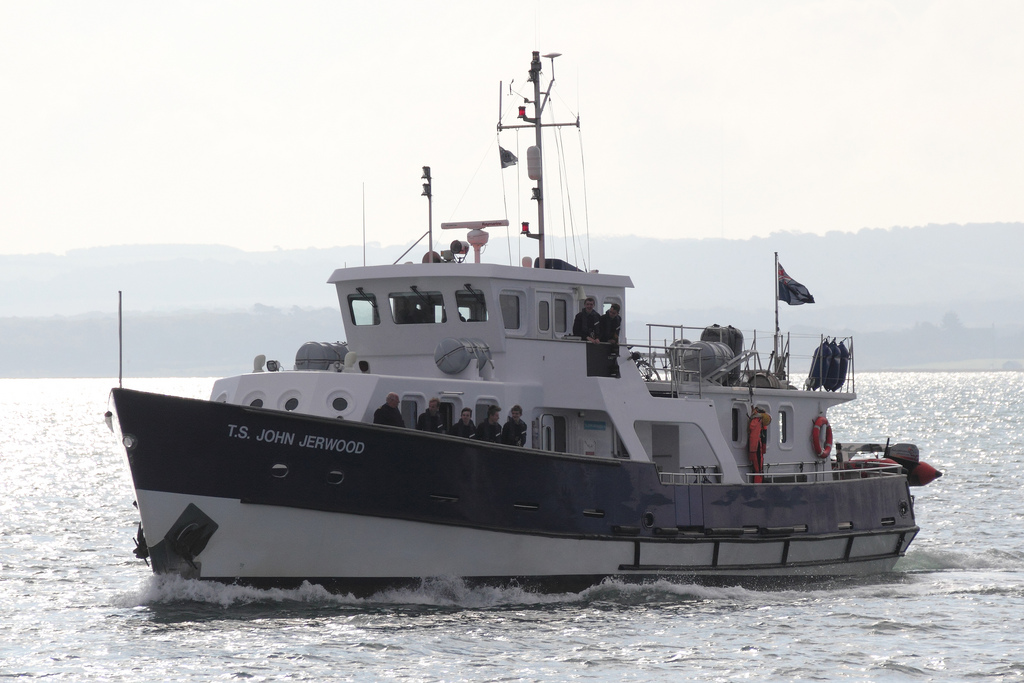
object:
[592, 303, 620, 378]
people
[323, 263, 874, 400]
level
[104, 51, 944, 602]
boat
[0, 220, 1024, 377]
shoreline